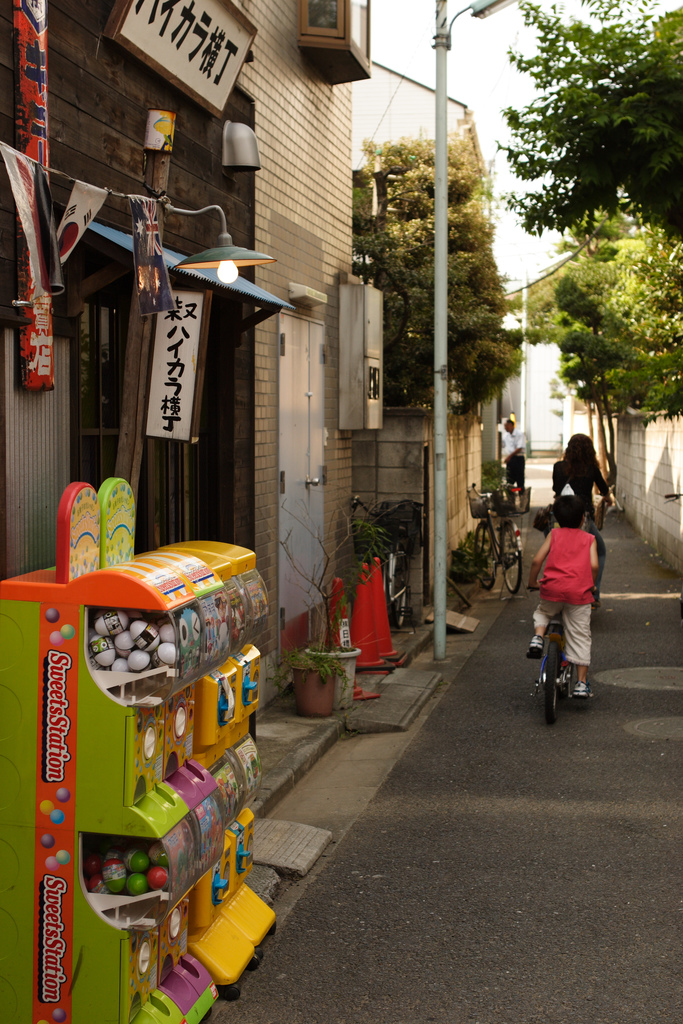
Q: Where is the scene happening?
A: On the street.